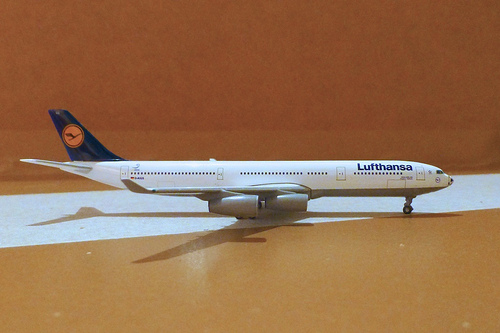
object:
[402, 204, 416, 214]
gear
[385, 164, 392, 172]
blue letter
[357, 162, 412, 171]
letter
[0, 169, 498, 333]
ground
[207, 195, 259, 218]
engine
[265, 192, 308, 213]
engine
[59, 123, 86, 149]
logo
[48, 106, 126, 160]
rudder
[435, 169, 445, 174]
cockpit wondow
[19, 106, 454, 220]
aircraft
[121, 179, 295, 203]
wing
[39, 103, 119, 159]
tail